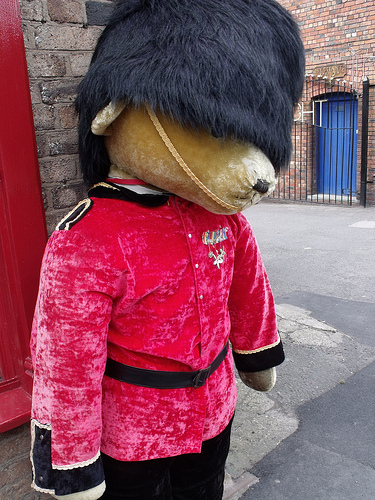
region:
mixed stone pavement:
[306, 352, 366, 484]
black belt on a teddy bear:
[101, 343, 242, 399]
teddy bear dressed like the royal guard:
[66, 11, 278, 397]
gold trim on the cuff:
[237, 339, 288, 355]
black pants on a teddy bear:
[119, 456, 236, 492]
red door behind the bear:
[12, 210, 46, 325]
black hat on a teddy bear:
[88, 8, 301, 146]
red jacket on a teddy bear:
[24, 207, 365, 460]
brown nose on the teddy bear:
[246, 164, 277, 199]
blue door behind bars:
[308, 80, 372, 203]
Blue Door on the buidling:
[307, 93, 357, 200]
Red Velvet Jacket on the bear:
[27, 184, 283, 493]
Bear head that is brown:
[83, 101, 278, 213]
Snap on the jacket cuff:
[35, 431, 44, 439]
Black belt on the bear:
[105, 346, 229, 386]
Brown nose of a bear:
[250, 178, 269, 193]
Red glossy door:
[0, 0, 45, 428]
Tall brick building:
[280, 1, 372, 200]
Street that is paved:
[244, 202, 371, 495]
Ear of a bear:
[90, 94, 125, 134]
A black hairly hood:
[100, 11, 318, 153]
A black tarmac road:
[268, 426, 373, 492]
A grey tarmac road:
[280, 307, 344, 387]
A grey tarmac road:
[282, 246, 353, 289]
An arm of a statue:
[28, 244, 119, 497]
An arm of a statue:
[242, 247, 287, 385]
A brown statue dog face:
[97, 109, 274, 225]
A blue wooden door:
[316, 100, 353, 196]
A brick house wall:
[314, 3, 374, 77]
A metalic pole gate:
[309, 77, 374, 205]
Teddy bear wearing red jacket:
[69, 210, 246, 423]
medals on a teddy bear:
[187, 232, 240, 284]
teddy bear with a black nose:
[235, 173, 281, 208]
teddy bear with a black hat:
[115, 30, 296, 147]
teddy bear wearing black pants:
[107, 369, 235, 496]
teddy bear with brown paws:
[248, 369, 276, 399]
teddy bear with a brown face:
[129, 122, 214, 191]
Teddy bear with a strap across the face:
[136, 93, 242, 218]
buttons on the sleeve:
[19, 424, 63, 488]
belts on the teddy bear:
[137, 370, 229, 416]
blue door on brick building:
[305, 89, 366, 200]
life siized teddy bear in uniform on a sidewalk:
[14, 0, 313, 498]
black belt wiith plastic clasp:
[105, 339, 233, 393]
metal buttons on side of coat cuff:
[31, 426, 49, 490]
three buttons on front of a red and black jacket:
[183, 228, 214, 313]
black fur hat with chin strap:
[71, 0, 313, 226]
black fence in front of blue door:
[263, 69, 366, 212]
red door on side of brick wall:
[1, 0, 65, 449]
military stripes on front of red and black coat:
[196, 220, 239, 273]